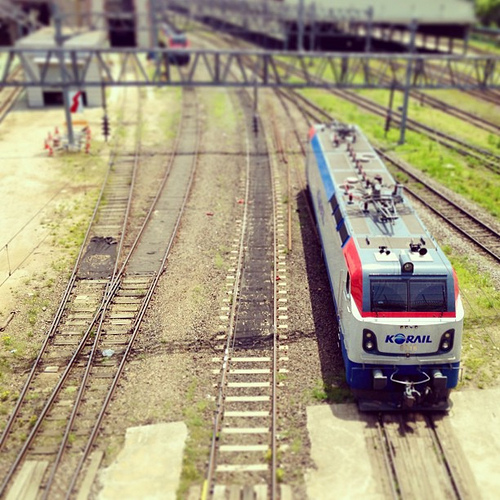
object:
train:
[300, 120, 465, 417]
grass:
[183, 425, 204, 453]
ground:
[0, 12, 499, 500]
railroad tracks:
[201, 353, 277, 499]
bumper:
[386, 367, 431, 389]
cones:
[39, 122, 95, 158]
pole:
[61, 82, 76, 144]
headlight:
[440, 338, 450, 353]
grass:
[311, 379, 350, 406]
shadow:
[295, 186, 449, 438]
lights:
[364, 340, 372, 350]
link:
[368, 364, 451, 410]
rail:
[379, 415, 462, 498]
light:
[400, 260, 414, 275]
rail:
[0, 40, 497, 90]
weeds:
[424, 151, 459, 178]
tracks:
[372, 145, 500, 267]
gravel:
[166, 303, 186, 321]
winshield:
[366, 277, 445, 312]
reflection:
[372, 281, 408, 314]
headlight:
[363, 328, 374, 337]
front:
[350, 321, 462, 364]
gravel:
[306, 316, 323, 344]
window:
[370, 277, 410, 312]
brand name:
[383, 332, 435, 347]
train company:
[381, 332, 429, 344]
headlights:
[440, 340, 447, 351]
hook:
[377, 370, 446, 408]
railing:
[0, 45, 497, 62]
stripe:
[308, 133, 339, 203]